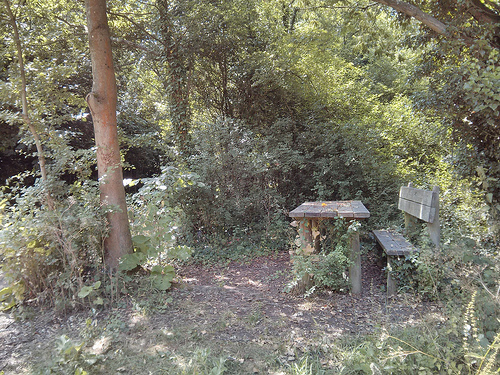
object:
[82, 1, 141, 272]
trunk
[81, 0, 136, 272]
tree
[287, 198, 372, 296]
table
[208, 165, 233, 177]
woods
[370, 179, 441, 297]
bench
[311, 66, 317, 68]
leaves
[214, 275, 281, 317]
dirt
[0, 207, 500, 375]
ground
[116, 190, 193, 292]
weeds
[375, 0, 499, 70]
branch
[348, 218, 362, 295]
legs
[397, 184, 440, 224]
back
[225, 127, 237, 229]
shrubs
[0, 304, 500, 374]
grass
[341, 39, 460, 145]
vegetation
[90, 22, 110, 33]
stem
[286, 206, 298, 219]
edge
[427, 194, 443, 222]
edge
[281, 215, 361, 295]
plant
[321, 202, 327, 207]
leaf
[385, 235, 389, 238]
leaves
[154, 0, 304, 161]
plant